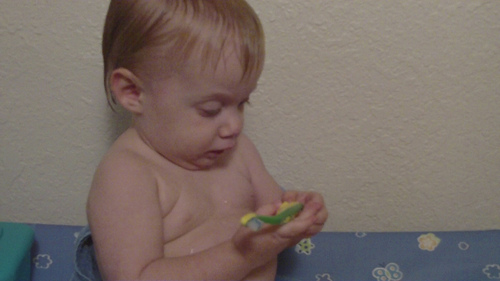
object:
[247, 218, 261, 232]
white bristles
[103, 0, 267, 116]
hair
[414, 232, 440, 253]
flower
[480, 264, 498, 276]
flower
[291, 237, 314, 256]
flower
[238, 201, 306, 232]
toothbrush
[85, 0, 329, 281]
baby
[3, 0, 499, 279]
bathroom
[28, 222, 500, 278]
bumper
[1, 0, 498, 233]
wall